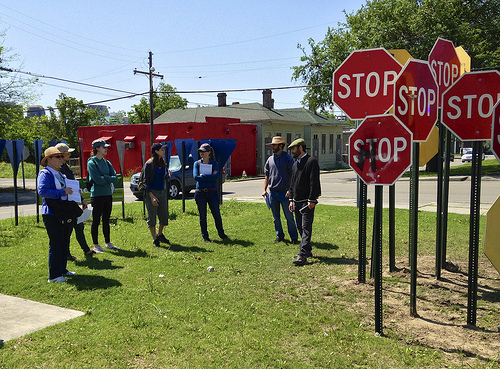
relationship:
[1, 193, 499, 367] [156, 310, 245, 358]
grass in area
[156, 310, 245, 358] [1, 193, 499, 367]
area with grass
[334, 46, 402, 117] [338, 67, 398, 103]
sign to stop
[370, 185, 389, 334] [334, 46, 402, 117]
post for sign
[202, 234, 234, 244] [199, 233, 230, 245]
feet in shoes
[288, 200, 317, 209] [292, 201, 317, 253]
hands and pants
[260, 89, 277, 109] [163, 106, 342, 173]
chimney in building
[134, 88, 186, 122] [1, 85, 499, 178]
tree in back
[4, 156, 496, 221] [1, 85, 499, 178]
road in back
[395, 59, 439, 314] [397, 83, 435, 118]
signpost indicates stop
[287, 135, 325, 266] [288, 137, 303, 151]
person wearing hat